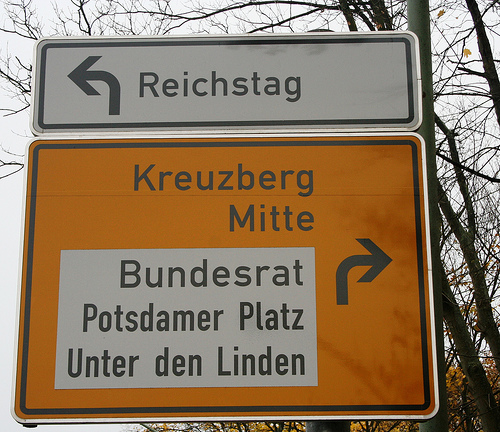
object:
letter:
[139, 71, 160, 97]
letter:
[162, 78, 179, 97]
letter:
[183, 72, 189, 97]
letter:
[192, 78, 209, 97]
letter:
[211, 70, 227, 96]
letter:
[232, 77, 250, 97]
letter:
[251, 72, 261, 95]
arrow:
[66, 55, 121, 117]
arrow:
[335, 238, 393, 306]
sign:
[30, 30, 422, 136]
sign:
[10, 131, 442, 427]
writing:
[139, 71, 301, 103]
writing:
[134, 163, 315, 232]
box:
[53, 246, 318, 390]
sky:
[0, 0, 499, 432]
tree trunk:
[464, 0, 500, 122]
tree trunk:
[434, 111, 500, 366]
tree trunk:
[335, 0, 499, 432]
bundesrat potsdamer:
[83, 259, 304, 333]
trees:
[0, 0, 498, 432]